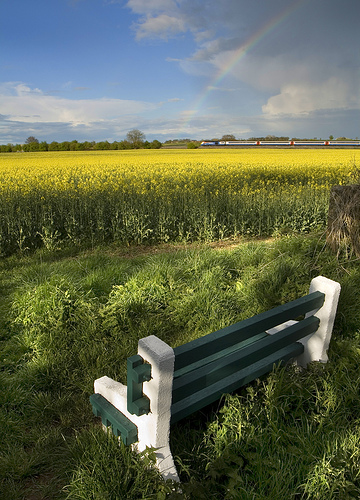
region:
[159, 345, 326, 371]
Back of bench is green.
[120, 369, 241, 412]
Seat on bench is green.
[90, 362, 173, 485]
Leg on bench is white.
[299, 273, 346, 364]
Leg on bench is white.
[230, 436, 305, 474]
Grass near bench is green.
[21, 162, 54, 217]
Yellow flowers in field near bench.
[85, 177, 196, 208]
Tall flowers in field near bench.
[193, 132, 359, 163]
Train driving in distance.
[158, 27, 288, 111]
Rainbow in sky in background.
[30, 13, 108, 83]
Sky is clear and blue.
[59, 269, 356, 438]
a long blue bench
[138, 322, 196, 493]
a white stone in grass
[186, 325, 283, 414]
a series of sticks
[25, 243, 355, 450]
a beautiful view of grass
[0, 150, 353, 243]
a greenish garden in earth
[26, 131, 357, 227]
a super view of plants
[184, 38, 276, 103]
rainbow in the sky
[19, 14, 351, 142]
a clear view of sky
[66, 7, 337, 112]
white clouds in the sky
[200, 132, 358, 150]
a long train passing by